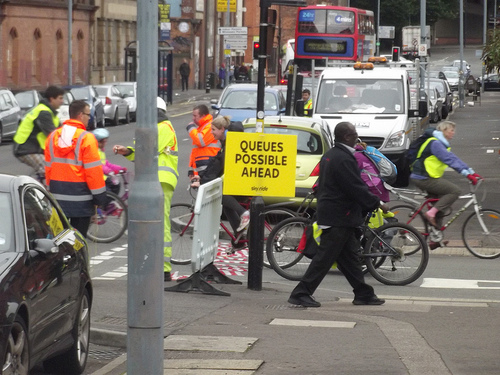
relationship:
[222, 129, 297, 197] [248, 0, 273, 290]
sign on a black pole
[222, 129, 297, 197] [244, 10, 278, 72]
sign on a pole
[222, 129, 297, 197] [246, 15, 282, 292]
sign on a black pole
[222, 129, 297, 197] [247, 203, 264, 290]
sign on a pole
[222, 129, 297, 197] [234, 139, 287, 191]
sign with words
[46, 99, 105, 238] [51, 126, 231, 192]
man wearing coats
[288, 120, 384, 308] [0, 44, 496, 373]
man on street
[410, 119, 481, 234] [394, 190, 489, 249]
man on bike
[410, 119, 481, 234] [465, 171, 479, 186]
man wears gloves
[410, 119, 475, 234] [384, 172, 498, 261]
man rides bicycle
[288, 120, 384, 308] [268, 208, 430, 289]
man rides bicycle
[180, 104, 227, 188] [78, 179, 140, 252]
man rides bicycle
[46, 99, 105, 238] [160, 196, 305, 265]
man rides bicycle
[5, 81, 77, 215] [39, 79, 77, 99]
man wears hat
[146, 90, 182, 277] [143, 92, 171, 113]
man wears hat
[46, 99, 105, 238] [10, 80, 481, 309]
man in foreground people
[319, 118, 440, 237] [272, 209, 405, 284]
people on bikes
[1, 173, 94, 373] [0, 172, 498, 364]
black car on foreground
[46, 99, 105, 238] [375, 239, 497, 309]
man on crosswalk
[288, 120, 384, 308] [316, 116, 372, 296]
man has side view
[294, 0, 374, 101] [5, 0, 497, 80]
bus on background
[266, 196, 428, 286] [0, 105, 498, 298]
bike on street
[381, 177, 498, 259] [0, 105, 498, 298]
bike on street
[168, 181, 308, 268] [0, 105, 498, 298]
bike on street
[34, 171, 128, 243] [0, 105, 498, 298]
bike on street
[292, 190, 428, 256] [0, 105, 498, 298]
bike on street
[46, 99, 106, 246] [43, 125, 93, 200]
man wears coat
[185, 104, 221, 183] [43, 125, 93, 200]
man wears coat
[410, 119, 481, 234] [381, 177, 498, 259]
man riding bike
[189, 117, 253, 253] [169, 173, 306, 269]
person riding bike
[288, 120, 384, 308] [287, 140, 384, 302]
man dressed in black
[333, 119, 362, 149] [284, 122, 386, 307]
head of man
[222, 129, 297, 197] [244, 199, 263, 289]
sign on pole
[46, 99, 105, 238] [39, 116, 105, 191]
man wearing coat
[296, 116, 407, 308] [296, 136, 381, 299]
man wearing suit